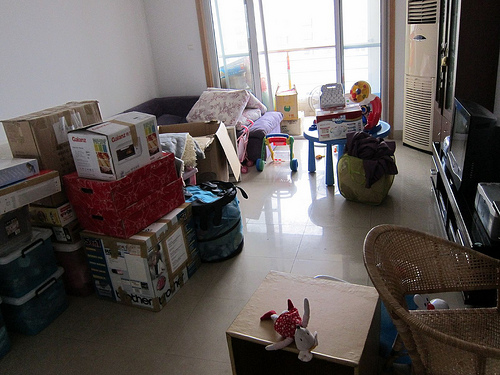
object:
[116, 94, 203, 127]
sofa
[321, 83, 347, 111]
lunch bag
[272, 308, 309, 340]
shirt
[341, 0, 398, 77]
window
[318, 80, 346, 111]
item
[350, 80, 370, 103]
item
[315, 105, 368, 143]
item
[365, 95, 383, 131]
item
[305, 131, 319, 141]
blue table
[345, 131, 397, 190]
clothes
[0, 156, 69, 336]
stacked bins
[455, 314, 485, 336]
seat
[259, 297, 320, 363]
doll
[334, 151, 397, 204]
hamper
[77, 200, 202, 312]
box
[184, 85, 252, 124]
cushion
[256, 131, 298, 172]
toy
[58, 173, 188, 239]
boxes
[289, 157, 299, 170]
wheel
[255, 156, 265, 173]
wheel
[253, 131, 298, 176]
walker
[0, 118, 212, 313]
bins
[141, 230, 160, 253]
tape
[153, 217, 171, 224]
tape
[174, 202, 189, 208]
tape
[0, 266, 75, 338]
bin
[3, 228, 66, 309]
bin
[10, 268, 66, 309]
lid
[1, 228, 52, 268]
lid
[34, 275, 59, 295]
handle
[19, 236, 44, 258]
handle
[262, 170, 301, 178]
ground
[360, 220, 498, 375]
back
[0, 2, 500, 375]
room